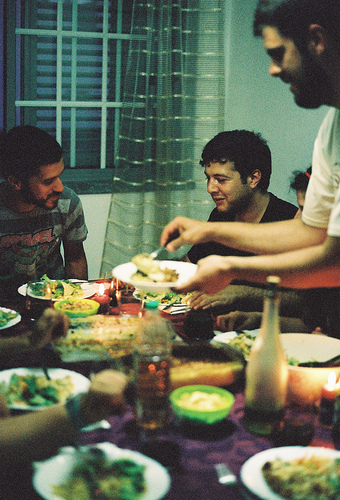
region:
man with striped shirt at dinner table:
[1, 120, 100, 338]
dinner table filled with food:
[0, 255, 243, 487]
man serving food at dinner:
[125, 20, 337, 312]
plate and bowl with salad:
[6, 260, 112, 320]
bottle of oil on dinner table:
[237, 259, 317, 453]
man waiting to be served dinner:
[106, 119, 307, 321]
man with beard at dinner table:
[3, 117, 108, 333]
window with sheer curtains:
[84, 5, 202, 217]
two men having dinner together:
[0, 93, 284, 320]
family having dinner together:
[1, 21, 339, 353]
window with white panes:
[14, 1, 192, 170]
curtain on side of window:
[99, 0, 224, 270]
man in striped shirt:
[1, 126, 88, 282]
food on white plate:
[18, 277, 96, 300]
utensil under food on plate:
[112, 247, 201, 291]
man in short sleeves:
[253, 1, 338, 242]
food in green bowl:
[169, 383, 235, 422]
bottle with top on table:
[242, 275, 285, 432]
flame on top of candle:
[94, 282, 109, 309]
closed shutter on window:
[31, 3, 128, 130]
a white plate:
[242, 466, 259, 481]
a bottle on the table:
[129, 327, 168, 425]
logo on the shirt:
[6, 234, 56, 272]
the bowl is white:
[300, 334, 323, 355]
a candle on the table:
[93, 291, 109, 304]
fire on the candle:
[94, 283, 105, 295]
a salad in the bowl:
[7, 372, 69, 405]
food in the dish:
[126, 252, 167, 283]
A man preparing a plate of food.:
[110, 1, 338, 293]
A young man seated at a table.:
[164, 128, 298, 267]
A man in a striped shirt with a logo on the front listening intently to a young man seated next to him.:
[0, 124, 91, 285]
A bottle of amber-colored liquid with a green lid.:
[134, 296, 172, 432]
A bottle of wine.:
[241, 274, 290, 431]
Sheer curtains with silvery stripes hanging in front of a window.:
[98, 1, 226, 280]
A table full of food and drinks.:
[1, 275, 339, 497]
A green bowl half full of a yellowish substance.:
[169, 381, 238, 433]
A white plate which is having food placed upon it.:
[108, 252, 201, 291]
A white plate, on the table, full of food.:
[239, 444, 338, 498]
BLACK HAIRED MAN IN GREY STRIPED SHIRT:
[0, 118, 90, 278]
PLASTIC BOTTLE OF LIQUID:
[135, 297, 176, 436]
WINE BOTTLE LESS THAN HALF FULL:
[242, 272, 290, 440]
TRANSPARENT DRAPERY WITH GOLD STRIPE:
[120, 116, 200, 215]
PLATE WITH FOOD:
[112, 251, 206, 294]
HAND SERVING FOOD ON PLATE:
[142, 214, 196, 258]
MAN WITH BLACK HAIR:
[196, 130, 278, 216]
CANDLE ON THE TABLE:
[316, 374, 339, 430]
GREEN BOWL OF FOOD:
[171, 384, 235, 431]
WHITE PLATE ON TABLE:
[282, 332, 339, 365]